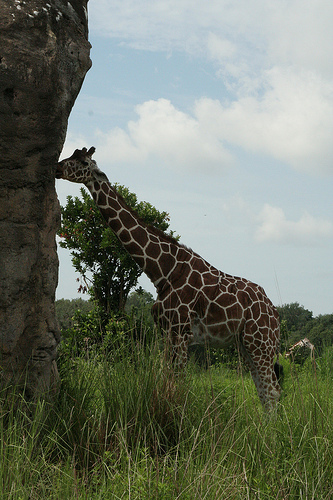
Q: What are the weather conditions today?
A: It is cloudy.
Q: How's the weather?
A: It is cloudy.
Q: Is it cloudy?
A: Yes, it is cloudy.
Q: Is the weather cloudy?
A: Yes, it is cloudy.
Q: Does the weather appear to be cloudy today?
A: Yes, it is cloudy.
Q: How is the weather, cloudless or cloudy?
A: It is cloudy.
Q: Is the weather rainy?
A: No, it is cloudy.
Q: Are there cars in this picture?
A: No, there are no cars.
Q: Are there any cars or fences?
A: No, there are no cars or fences.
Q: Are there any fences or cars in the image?
A: No, there are no cars or fences.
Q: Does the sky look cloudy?
A: Yes, the sky is cloudy.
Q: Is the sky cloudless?
A: No, the sky is cloudy.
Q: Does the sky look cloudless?
A: No, the sky is cloudy.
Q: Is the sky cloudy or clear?
A: The sky is cloudy.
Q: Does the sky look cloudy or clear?
A: The sky is cloudy.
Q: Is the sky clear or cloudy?
A: The sky is cloudy.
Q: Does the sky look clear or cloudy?
A: The sky is cloudy.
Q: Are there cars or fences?
A: No, there are no fences or cars.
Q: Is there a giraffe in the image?
A: Yes, there is a giraffe.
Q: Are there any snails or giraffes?
A: Yes, there is a giraffe.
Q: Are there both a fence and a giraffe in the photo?
A: No, there is a giraffe but no fences.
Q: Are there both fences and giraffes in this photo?
A: No, there is a giraffe but no fences.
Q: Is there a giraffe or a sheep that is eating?
A: Yes, the giraffe is eating.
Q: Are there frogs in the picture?
A: No, there are no frogs.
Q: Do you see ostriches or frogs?
A: No, there are no frogs or ostriches.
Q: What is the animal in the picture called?
A: The animal is a giraffe.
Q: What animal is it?
A: The animal is a giraffe.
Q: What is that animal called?
A: This is a giraffe.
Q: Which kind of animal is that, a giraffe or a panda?
A: This is a giraffe.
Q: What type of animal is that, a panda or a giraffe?
A: This is a giraffe.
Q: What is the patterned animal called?
A: The animal is a giraffe.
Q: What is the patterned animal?
A: The animal is a giraffe.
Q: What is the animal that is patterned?
A: The animal is a giraffe.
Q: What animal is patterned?
A: The animal is a giraffe.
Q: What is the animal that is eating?
A: The animal is a giraffe.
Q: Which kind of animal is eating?
A: The animal is a giraffe.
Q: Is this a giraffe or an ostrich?
A: This is a giraffe.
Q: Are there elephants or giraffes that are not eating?
A: No, there is a giraffe but it is eating.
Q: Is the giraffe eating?
A: Yes, the giraffe is eating.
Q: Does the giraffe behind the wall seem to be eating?
A: Yes, the giraffe is eating.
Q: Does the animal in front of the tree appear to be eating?
A: Yes, the giraffe is eating.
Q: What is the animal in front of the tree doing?
A: The giraffe is eating.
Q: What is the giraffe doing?
A: The giraffe is eating.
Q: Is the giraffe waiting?
A: No, the giraffe is eating.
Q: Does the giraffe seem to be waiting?
A: No, the giraffe is eating.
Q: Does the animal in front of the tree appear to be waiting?
A: No, the giraffe is eating.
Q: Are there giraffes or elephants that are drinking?
A: No, there is a giraffe but it is eating.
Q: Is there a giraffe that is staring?
A: No, there is a giraffe but it is eating.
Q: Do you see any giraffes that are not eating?
A: No, there is a giraffe but it is eating.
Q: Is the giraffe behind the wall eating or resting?
A: The giraffe is eating.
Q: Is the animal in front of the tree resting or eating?
A: The giraffe is eating.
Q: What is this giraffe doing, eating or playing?
A: The giraffe is eating.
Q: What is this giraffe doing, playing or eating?
A: The giraffe is eating.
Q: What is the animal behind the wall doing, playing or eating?
A: The giraffe is eating.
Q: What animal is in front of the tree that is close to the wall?
A: The animal is a giraffe.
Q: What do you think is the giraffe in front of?
A: The giraffe is in front of the tree.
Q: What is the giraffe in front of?
A: The giraffe is in front of the tree.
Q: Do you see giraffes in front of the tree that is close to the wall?
A: Yes, there is a giraffe in front of the tree.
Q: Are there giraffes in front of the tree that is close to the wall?
A: Yes, there is a giraffe in front of the tree.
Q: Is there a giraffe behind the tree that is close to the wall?
A: No, the giraffe is in front of the tree.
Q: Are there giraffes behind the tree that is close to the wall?
A: No, the giraffe is in front of the tree.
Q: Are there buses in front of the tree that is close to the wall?
A: No, there is a giraffe in front of the tree.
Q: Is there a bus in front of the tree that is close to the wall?
A: No, there is a giraffe in front of the tree.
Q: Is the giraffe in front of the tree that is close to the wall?
A: Yes, the giraffe is in front of the tree.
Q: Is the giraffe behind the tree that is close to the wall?
A: No, the giraffe is in front of the tree.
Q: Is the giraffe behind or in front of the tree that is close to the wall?
A: The giraffe is in front of the tree.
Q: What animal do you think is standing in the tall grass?
A: The giraffe is standing in the grass.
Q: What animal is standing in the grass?
A: The giraffe is standing in the grass.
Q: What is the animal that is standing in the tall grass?
A: The animal is a giraffe.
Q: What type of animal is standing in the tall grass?
A: The animal is a giraffe.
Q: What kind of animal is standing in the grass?
A: The animal is a giraffe.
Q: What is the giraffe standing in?
A: The giraffe is standing in the grass.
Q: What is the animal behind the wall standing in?
A: The giraffe is standing in the grass.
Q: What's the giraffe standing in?
A: The giraffe is standing in the grass.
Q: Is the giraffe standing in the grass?
A: Yes, the giraffe is standing in the grass.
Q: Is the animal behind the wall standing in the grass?
A: Yes, the giraffe is standing in the grass.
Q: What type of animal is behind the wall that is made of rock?
A: The animal is a giraffe.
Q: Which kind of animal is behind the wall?
A: The animal is a giraffe.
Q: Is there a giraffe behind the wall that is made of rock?
A: Yes, there is a giraffe behind the wall.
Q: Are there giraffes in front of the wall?
A: No, the giraffe is behind the wall.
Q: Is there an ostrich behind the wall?
A: No, there is a giraffe behind the wall.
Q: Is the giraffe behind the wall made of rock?
A: Yes, the giraffe is behind the wall.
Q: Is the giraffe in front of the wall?
A: No, the giraffe is behind the wall.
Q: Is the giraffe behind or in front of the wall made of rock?
A: The giraffe is behind the wall.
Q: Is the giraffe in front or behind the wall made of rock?
A: The giraffe is behind the wall.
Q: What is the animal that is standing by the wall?
A: The animal is a giraffe.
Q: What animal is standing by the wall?
A: The animal is a giraffe.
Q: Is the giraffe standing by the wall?
A: Yes, the giraffe is standing by the wall.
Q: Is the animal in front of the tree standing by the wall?
A: Yes, the giraffe is standing by the wall.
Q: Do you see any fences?
A: No, there are no fences.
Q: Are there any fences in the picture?
A: No, there are no fences.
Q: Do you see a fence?
A: No, there are no fences.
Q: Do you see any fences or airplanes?
A: No, there are no fences or airplanes.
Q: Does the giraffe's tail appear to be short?
A: Yes, the tail is short.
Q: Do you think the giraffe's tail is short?
A: Yes, the tail is short.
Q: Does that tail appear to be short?
A: Yes, the tail is short.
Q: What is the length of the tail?
A: The tail is short.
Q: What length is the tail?
A: The tail is short.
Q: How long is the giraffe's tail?
A: The tail is short.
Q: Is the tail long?
A: No, the tail is short.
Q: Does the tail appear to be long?
A: No, the tail is short.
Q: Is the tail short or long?
A: The tail is short.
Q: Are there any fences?
A: No, there are no fences.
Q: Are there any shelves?
A: No, there are no shelves.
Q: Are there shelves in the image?
A: No, there are no shelves.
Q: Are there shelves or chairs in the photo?
A: No, there are no shelves or chairs.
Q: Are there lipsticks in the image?
A: No, there are no lipsticks.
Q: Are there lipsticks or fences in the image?
A: No, there are no lipsticks or fences.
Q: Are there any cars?
A: No, there are no cars.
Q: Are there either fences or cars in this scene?
A: No, there are no cars or fences.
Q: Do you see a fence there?
A: No, there are no fences.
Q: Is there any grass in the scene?
A: Yes, there is grass.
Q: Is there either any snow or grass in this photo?
A: Yes, there is grass.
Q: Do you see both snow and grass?
A: No, there is grass but no snow.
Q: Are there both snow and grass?
A: No, there is grass but no snow.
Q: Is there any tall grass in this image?
A: Yes, there is tall grass.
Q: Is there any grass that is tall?
A: Yes, there is grass that is tall.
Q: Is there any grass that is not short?
A: Yes, there is tall grass.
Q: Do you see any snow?
A: No, there is no snow.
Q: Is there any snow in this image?
A: No, there is no snow.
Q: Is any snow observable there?
A: No, there is no snow.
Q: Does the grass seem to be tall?
A: Yes, the grass is tall.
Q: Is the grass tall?
A: Yes, the grass is tall.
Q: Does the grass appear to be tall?
A: Yes, the grass is tall.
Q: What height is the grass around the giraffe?
A: The grass is tall.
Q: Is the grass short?
A: No, the grass is tall.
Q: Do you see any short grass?
A: No, there is grass but it is tall.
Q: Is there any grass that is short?
A: No, there is grass but it is tall.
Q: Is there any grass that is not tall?
A: No, there is grass but it is tall.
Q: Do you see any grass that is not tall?
A: No, there is grass but it is tall.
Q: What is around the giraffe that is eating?
A: The grass is around the giraffe.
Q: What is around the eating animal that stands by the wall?
A: The grass is around the giraffe.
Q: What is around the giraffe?
A: The grass is around the giraffe.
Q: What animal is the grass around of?
A: The grass is around the giraffe.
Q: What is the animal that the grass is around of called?
A: The animal is a giraffe.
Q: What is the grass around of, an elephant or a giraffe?
A: The grass is around a giraffe.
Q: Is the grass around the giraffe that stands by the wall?
A: Yes, the grass is around the giraffe.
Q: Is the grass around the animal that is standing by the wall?
A: Yes, the grass is around the giraffe.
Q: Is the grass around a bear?
A: No, the grass is around the giraffe.